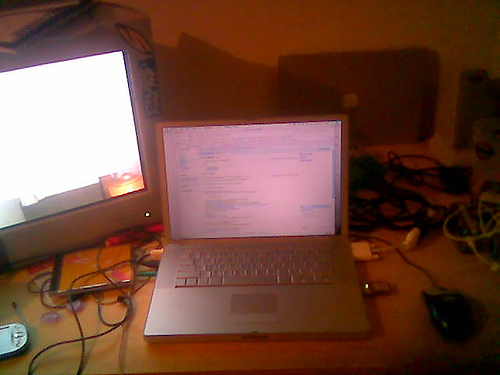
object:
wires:
[398, 154, 444, 167]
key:
[186, 277, 197, 286]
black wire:
[20, 338, 85, 375]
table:
[0, 136, 500, 375]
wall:
[148, 2, 499, 148]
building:
[0, 0, 500, 375]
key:
[222, 270, 233, 276]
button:
[278, 275, 291, 285]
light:
[364, 283, 369, 289]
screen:
[163, 117, 350, 236]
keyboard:
[173, 240, 338, 287]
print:
[162, 121, 340, 235]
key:
[222, 276, 277, 285]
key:
[292, 262, 303, 268]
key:
[175, 271, 201, 278]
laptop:
[141, 112, 374, 349]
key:
[194, 259, 204, 265]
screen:
[0, 50, 146, 234]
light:
[145, 212, 150, 217]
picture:
[98, 165, 146, 201]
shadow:
[150, 31, 374, 148]